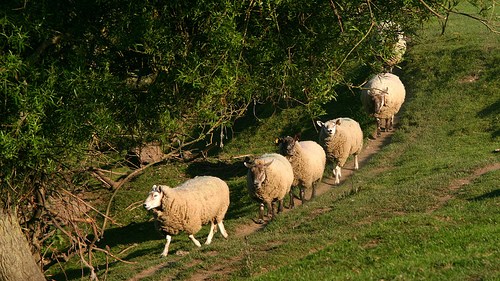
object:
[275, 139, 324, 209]
sheep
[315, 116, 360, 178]
sheep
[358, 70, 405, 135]
sheep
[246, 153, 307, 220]
sheep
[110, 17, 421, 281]
row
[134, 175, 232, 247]
sheep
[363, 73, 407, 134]
sheep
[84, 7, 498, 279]
grass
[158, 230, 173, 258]
leg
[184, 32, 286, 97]
leaves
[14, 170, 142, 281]
twigs/tree